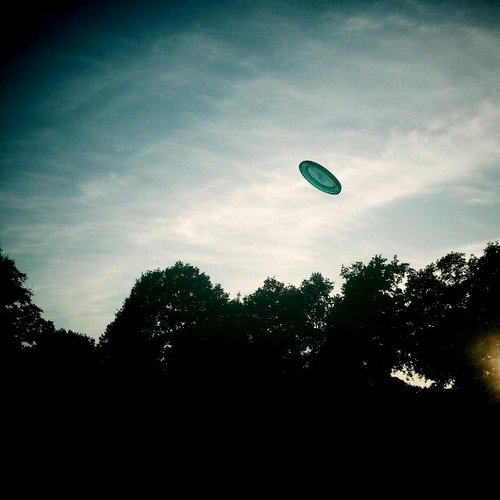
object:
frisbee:
[298, 160, 342, 197]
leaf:
[403, 262, 442, 313]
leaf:
[290, 289, 317, 316]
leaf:
[340, 335, 385, 390]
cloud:
[0, 8, 499, 330]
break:
[389, 367, 435, 389]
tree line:
[0, 240, 500, 409]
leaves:
[254, 283, 295, 309]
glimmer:
[471, 327, 500, 390]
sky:
[0, 0, 500, 344]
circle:
[298, 160, 342, 196]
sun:
[469, 330, 500, 398]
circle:
[307, 166, 335, 188]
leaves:
[168, 277, 257, 330]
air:
[0, 0, 500, 447]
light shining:
[388, 362, 457, 393]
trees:
[0, 244, 499, 499]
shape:
[298, 159, 341, 195]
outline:
[0, 241, 500, 387]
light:
[471, 328, 500, 397]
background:
[3, 177, 484, 383]